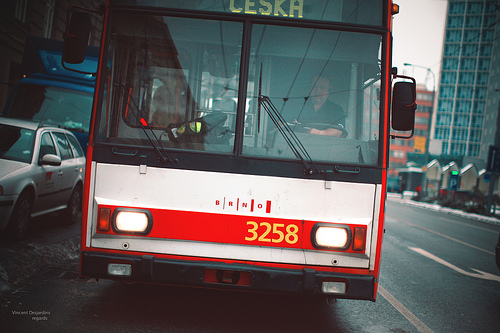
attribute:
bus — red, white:
[75, 0, 413, 304]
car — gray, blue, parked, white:
[1, 113, 88, 242]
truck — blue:
[3, 30, 114, 202]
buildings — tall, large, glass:
[424, 0, 500, 180]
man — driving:
[285, 64, 354, 143]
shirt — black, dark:
[287, 99, 354, 142]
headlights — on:
[309, 224, 353, 255]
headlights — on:
[108, 207, 152, 237]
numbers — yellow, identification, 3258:
[243, 220, 302, 247]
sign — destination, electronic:
[224, 0, 307, 21]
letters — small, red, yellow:
[213, 197, 266, 211]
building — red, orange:
[2, 1, 128, 158]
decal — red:
[41, 170, 54, 184]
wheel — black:
[290, 119, 349, 140]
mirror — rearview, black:
[203, 51, 237, 78]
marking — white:
[407, 240, 500, 287]